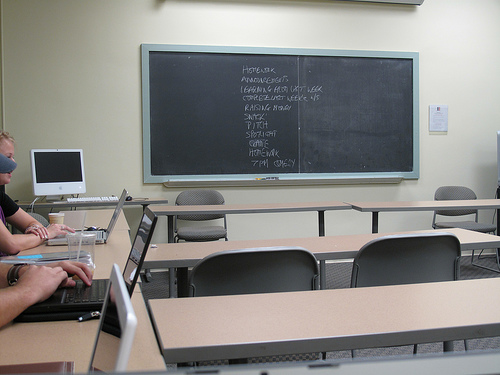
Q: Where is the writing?
A: On the board.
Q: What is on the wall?
A: The chalkboard.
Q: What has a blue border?
A: The chalkboard.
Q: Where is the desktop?
A: On a desk.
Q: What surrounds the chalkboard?
A: A frame.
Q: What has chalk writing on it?
A: The chalkboard.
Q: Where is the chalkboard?
A: On the wall.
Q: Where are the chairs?
A: At the tables.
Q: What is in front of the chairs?
A: Tables.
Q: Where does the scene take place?
A: In a classroom.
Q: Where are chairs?
A: Near the tables.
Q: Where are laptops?
A: On a table.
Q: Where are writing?
A: On a chalkboard.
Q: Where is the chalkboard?
A: On the wall.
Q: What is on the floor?
A: A carpet.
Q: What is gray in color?
A: Chairs.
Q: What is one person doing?
A: Typing on laptop.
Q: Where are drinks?
A: On a table.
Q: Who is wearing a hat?
A: Person typing.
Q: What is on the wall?
A: Chalkboard.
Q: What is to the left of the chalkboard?
A: Computer.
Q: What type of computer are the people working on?
A: Laptops.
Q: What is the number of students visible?
A: 2.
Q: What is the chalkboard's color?
A: Black.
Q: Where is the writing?
A: On the chalkboard.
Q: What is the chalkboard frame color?
A: Silver.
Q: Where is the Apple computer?
A: Front of the classroom.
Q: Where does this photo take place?
A: A classroom.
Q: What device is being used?
A: Laptop.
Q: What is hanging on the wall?
A: A chalkboard.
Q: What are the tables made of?
A: Wood.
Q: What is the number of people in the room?
A: Two.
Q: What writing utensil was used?
A: Chalk.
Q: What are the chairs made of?
A: Metal.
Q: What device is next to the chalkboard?
A: Apple computer.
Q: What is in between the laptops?
A: A plastic cup.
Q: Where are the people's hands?
A: On the laptop.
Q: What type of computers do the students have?
A: Laptops.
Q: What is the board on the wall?
A: Chalk board.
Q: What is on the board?
A: Writing.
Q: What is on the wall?
A: Board.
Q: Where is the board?
A: On the wall.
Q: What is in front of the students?
A: Computers.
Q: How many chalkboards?
A: 1.